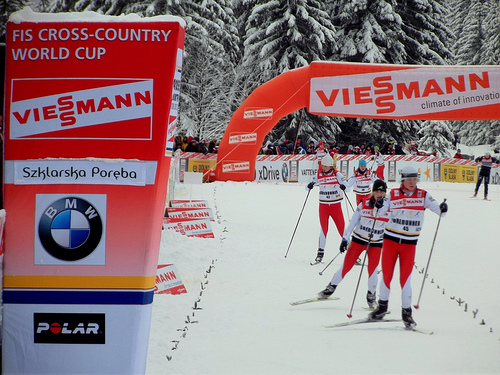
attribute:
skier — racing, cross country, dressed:
[367, 162, 447, 329]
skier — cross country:
[319, 177, 390, 310]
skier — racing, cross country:
[307, 154, 347, 265]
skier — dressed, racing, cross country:
[342, 160, 384, 212]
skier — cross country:
[472, 153, 498, 198]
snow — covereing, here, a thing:
[155, 172, 499, 374]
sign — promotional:
[218, 60, 498, 183]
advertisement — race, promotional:
[162, 217, 217, 240]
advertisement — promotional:
[153, 259, 187, 295]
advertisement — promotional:
[34, 192, 107, 262]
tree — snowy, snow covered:
[233, 1, 405, 161]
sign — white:
[170, 199, 210, 208]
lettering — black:
[256, 165, 278, 180]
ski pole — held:
[418, 197, 447, 309]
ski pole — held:
[347, 206, 381, 319]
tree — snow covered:
[399, 1, 498, 157]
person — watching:
[294, 140, 306, 157]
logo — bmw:
[45, 198, 97, 224]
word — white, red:
[37, 321, 101, 336]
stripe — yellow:
[1, 275, 157, 290]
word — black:
[22, 164, 86, 182]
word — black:
[91, 164, 137, 179]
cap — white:
[322, 153, 336, 167]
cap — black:
[372, 179, 387, 192]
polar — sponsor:
[34, 311, 106, 346]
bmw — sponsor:
[38, 197, 101, 258]